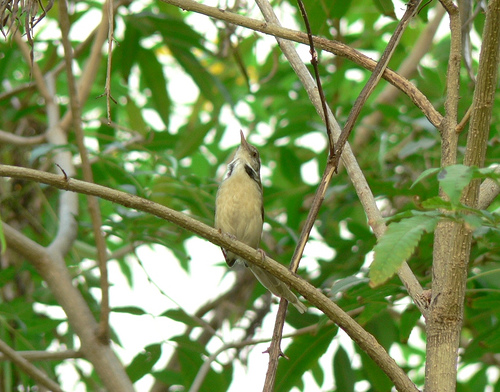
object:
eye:
[251, 152, 258, 159]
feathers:
[221, 179, 259, 233]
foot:
[258, 251, 269, 262]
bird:
[213, 129, 309, 317]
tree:
[0, 0, 499, 391]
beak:
[239, 129, 246, 146]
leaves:
[126, 156, 154, 188]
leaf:
[135, 45, 175, 130]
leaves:
[274, 294, 307, 329]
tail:
[245, 247, 314, 314]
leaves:
[133, 170, 187, 235]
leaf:
[271, 111, 300, 166]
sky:
[0, 0, 497, 391]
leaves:
[475, 240, 498, 277]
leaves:
[0, 293, 63, 348]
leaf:
[356, 302, 401, 389]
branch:
[0, 0, 260, 392]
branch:
[258, 0, 499, 389]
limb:
[0, 162, 417, 392]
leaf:
[365, 209, 427, 289]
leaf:
[269, 324, 338, 389]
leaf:
[438, 163, 473, 211]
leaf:
[138, 0, 182, 15]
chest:
[216, 179, 260, 238]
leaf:
[225, 33, 266, 105]